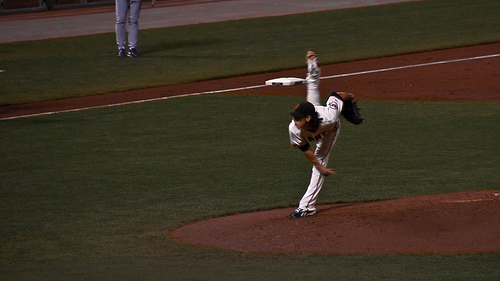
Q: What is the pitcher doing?
A: Pitching a ball.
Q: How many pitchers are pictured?
A: One.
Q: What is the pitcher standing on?
A: The pitcher's mound.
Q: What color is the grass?
A: Green.